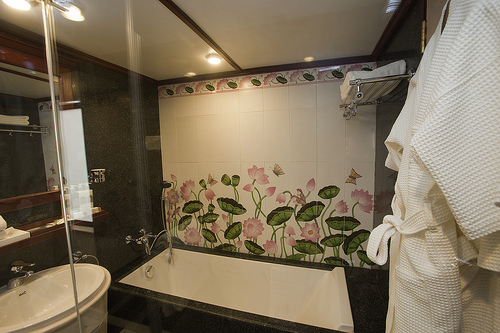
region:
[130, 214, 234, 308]
A bathtub is visible.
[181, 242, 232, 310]
A bathtub is visible.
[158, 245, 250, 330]
A bathtub is visible.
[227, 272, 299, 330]
A bathtub is visible.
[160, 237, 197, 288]
A bathtub is visible.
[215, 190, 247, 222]
green leaves painted on the wall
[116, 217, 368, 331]
large white bathtub in the bathroom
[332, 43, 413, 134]
a storage shelf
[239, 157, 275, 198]
pink flowers painted on the bathroom wall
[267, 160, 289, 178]
butterfly on the bathtub wall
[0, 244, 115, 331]
a deep sink in the bathroom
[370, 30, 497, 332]
a robe hanging up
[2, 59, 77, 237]
a mirror in the bathroom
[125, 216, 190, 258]
the bathtub spout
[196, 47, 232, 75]
a light over the bathtub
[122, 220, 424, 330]
white marble big bathtub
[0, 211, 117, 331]
oval shaped white sink with silver faucet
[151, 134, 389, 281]
pink and green design on white tile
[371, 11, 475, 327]
white robe with front tied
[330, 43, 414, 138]
white towel on silver shelf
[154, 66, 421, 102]
pink and green design at top of wall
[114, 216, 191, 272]
silver faucet over tub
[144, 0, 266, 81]
brown line on ceiling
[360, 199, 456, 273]
white straps on robe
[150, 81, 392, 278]
white tile wall with design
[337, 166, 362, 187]
a butterfly painted on tile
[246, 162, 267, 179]
a pink flower painted on tile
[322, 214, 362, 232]
a green lily pad painted on tile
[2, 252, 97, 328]
a white sink in a bathroom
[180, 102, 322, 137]
a white tile wall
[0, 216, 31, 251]
a soap dish above a sink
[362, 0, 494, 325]
a white bathrobe hanging up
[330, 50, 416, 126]
a metal rack holding a towel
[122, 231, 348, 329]
a white bathtub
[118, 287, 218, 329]
dark grey tile lining a bathtub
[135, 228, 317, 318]
A bathtub is visible.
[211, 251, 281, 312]
A bathtub is visible.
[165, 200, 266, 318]
A bathtub is visible.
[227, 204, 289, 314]
A bathtub is visible.